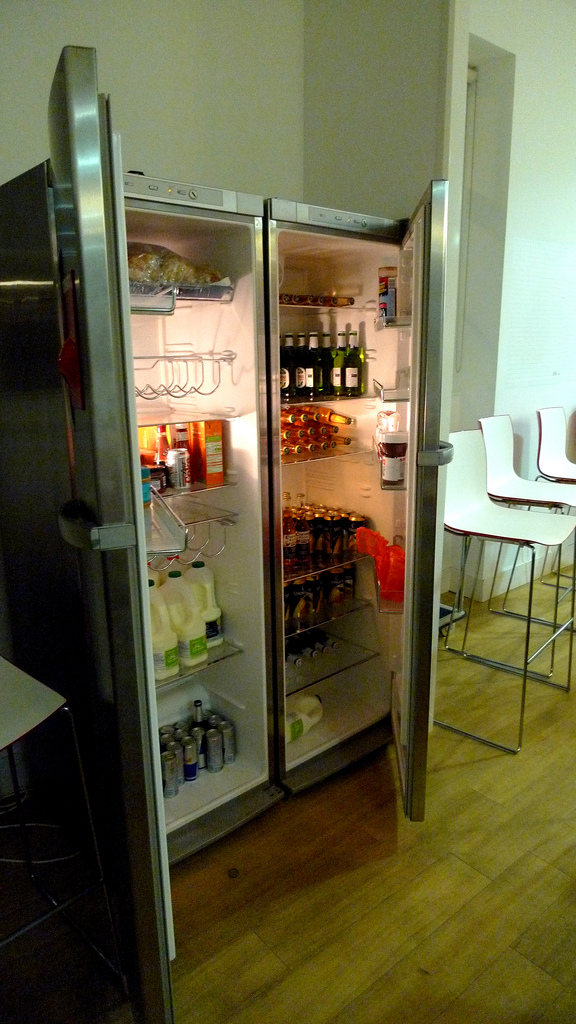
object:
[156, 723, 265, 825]
shelf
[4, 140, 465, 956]
refrigerator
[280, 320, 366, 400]
beer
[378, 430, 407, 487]
jar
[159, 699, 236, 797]
beer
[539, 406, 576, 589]
chair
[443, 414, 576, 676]
chair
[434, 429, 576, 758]
chair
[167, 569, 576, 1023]
floor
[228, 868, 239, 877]
knot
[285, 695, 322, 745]
jug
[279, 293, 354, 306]
bottles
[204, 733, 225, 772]
red bull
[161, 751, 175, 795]
red bull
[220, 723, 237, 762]
red bull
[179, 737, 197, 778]
red bull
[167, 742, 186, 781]
red bull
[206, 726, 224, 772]
red bull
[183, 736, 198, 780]
red bull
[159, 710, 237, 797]
redbull cans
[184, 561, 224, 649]
milk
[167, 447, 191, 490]
diet coke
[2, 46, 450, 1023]
refrigerator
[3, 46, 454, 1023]
fridge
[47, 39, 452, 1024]
doors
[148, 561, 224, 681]
jug